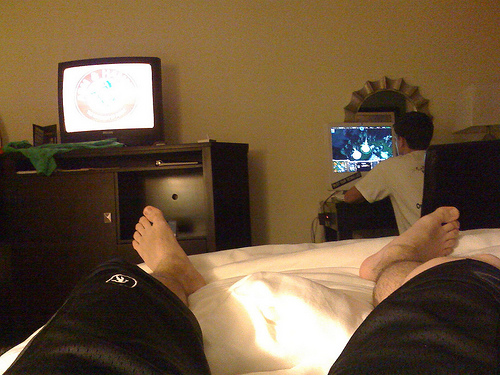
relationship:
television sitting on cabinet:
[54, 54, 169, 141] [5, 145, 253, 336]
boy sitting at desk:
[346, 116, 433, 231] [319, 202, 402, 242]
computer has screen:
[326, 123, 397, 200] [333, 126, 393, 171]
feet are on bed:
[130, 205, 479, 279] [4, 227, 499, 374]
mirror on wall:
[339, 77, 435, 128] [202, 15, 339, 123]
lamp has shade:
[448, 84, 499, 144] [457, 83, 497, 128]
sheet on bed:
[192, 241, 371, 374] [4, 227, 499, 374]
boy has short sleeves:
[346, 116, 433, 231] [356, 149, 429, 230]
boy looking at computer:
[346, 116, 433, 231] [326, 123, 397, 200]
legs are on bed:
[6, 261, 498, 373] [4, 227, 499, 374]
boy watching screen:
[346, 116, 433, 231] [333, 126, 393, 171]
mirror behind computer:
[339, 77, 435, 128] [326, 123, 397, 200]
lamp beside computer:
[448, 84, 499, 144] [326, 123, 397, 200]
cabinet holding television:
[5, 145, 253, 336] [54, 54, 169, 141]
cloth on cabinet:
[7, 139, 121, 171] [5, 145, 253, 336]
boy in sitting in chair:
[346, 116, 433, 231] [424, 144, 500, 234]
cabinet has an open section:
[5, 145, 253, 336] [118, 171, 213, 235]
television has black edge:
[54, 54, 169, 141] [61, 128, 167, 144]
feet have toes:
[130, 205, 479, 279] [120, 205, 185, 246]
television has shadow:
[54, 54, 169, 141] [162, 64, 184, 145]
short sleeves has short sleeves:
[356, 149, 429, 230] [356, 162, 387, 207]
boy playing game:
[346, 116, 433, 231] [336, 132, 391, 172]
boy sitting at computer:
[346, 116, 433, 231] [326, 123, 397, 200]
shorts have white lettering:
[7, 258, 500, 375] [106, 275, 137, 292]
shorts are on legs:
[7, 258, 500, 375] [6, 261, 498, 373]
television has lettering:
[54, 54, 169, 141] [101, 130, 115, 138]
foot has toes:
[361, 205, 479, 272] [431, 203, 461, 254]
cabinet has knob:
[5, 145, 253, 336] [97, 211, 115, 225]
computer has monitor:
[326, 123, 397, 200] [323, 120, 397, 189]